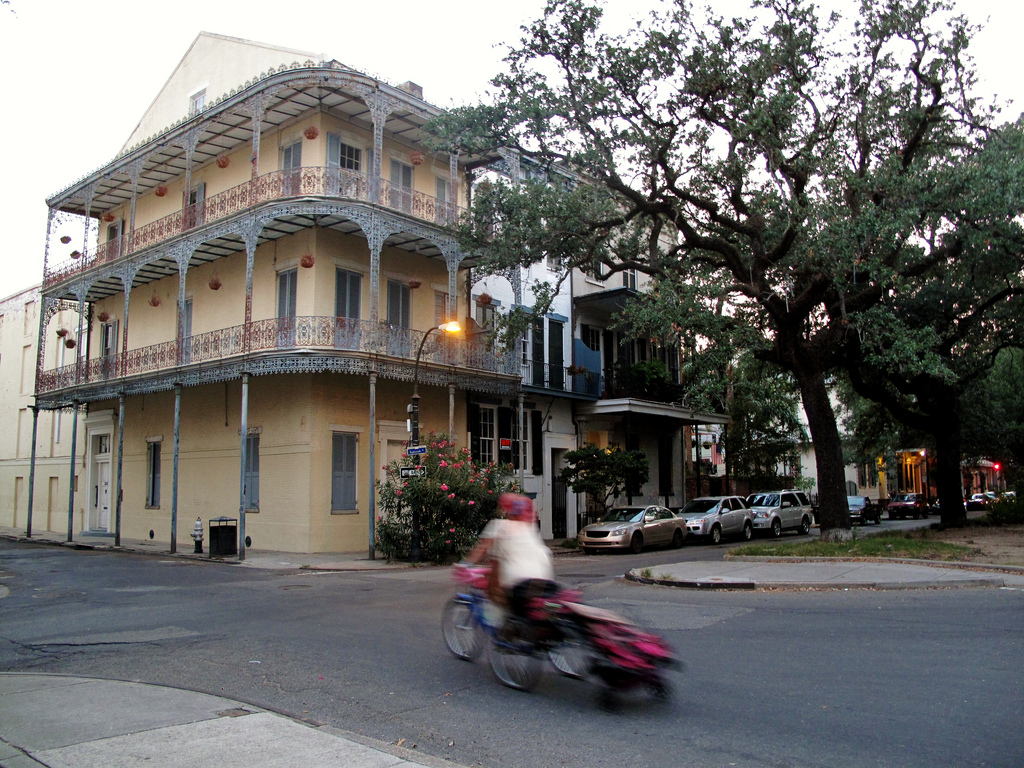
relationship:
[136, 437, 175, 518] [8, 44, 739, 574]
window on building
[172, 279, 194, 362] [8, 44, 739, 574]
window on building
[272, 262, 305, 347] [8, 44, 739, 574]
window on building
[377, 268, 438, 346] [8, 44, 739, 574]
window on building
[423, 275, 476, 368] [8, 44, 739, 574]
window on building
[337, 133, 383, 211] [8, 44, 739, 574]
window on building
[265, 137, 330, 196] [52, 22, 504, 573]
window of house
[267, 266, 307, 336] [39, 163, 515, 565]
window of house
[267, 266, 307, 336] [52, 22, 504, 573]
window of house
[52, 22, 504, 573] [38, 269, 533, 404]
house with balcony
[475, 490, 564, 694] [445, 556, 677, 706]
person on tricycle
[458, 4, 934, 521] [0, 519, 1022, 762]
tree beside road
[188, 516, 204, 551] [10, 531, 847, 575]
hydrant on sidewalk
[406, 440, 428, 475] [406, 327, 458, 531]
sign on pole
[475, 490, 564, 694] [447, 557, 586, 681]
person riding bike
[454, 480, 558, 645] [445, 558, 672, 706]
man on a motorcycle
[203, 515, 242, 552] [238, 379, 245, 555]
trash can next to pole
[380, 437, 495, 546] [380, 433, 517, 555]
flowers on plant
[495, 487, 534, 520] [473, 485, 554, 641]
hat on girl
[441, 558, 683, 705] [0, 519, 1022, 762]
cycle on road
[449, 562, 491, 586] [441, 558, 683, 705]
cloth on cycle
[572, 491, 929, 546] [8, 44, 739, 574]
cars near building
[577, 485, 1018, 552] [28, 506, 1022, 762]
cars on street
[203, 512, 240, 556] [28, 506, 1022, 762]
trash can on street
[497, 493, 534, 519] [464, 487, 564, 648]
helmet on person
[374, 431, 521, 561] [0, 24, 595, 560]
rose bush next to building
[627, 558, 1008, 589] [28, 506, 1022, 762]
curb next to street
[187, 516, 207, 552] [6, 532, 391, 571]
hydrant by curb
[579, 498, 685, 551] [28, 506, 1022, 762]
car in street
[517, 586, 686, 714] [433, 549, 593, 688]
trailer pulled by tricycle